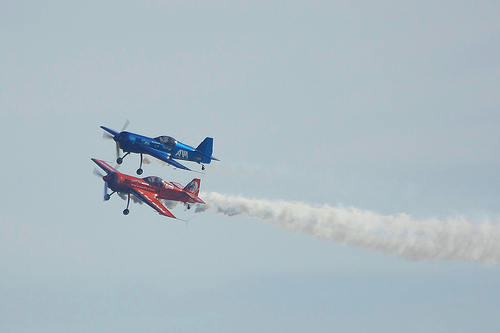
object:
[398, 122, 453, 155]
sky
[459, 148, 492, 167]
sky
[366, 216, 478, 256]
smoke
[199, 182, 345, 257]
smoke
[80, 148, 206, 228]
aircraft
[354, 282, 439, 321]
sky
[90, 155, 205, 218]
plane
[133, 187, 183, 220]
wing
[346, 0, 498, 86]
sky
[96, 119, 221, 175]
plane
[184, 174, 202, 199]
tail fin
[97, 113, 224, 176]
aircraft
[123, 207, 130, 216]
wheel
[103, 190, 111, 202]
front wheel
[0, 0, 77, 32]
sky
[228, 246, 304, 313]
sky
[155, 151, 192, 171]
wing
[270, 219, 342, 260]
section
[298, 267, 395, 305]
section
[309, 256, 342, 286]
sky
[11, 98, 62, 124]
sky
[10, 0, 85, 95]
section